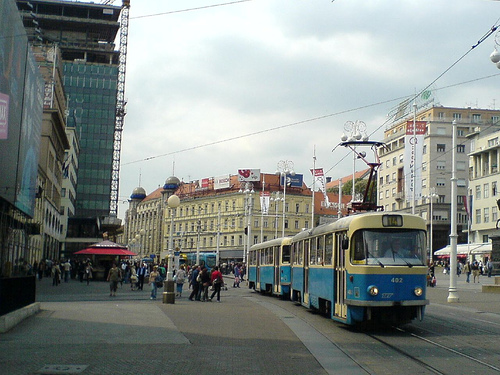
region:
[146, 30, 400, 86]
The clouds are the color white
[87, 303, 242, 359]
The ground is made of cement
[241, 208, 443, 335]
The train is on the tracks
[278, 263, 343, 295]
The train is the color blue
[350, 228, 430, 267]
The windshield on the front of the bus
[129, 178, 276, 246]
The building is the color yellow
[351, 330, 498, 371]
The train tracks on the ground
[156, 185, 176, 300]
The street light in the ground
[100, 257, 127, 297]
A person walking down the street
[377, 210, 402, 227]
The number of the bus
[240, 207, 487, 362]
Trolley car on tracks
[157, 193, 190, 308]
White and gold lamp post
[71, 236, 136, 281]
Red canopy behind people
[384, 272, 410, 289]
White numbers on front car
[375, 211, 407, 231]
Number fourteen on front of trolley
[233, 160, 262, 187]
Sign on roof of building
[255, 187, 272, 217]
Sign hanging on white pole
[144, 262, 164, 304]
Woman wearing blue jeans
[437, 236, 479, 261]
White awning on building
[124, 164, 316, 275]
Large building in background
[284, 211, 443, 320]
A bus parked near a sidewalk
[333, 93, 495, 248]
A tall multi story building.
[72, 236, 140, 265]
a red covering at the base of a building.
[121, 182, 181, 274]
a multi story building near a street.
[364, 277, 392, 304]
a right front headlight.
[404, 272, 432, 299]
a left front headlight.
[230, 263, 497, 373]
a paved road near buildings.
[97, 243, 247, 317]
a crowd of people on a sidewalk.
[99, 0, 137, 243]
a tall metal tower.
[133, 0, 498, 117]
A large gray cloud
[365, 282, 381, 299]
round halogen train headlight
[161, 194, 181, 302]
white lamp post set in concrete skirt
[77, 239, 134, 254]
red and white street stall umbrella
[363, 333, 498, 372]
train tracks set in street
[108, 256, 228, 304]
group of people walking on sidewalk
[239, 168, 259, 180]
advertising billboard on building roof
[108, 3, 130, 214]
scaffolding along side of building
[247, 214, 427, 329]
white and blue electric train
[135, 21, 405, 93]
turbulent white and blue overcast sky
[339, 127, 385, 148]
white bulb street lights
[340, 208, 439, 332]
A yellow and blue trail train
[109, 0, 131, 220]
A metal scaffold against the building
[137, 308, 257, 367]
A gray asphalt street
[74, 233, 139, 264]
A red and pink umbrella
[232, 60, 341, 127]
Blue, cloudy skies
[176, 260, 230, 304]
A group of people on the street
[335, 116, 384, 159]
A set of three white lights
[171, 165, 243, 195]
Alot of poster boards on top of the building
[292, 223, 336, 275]
Side windows of a bus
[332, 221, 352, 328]
Double doors of a bus